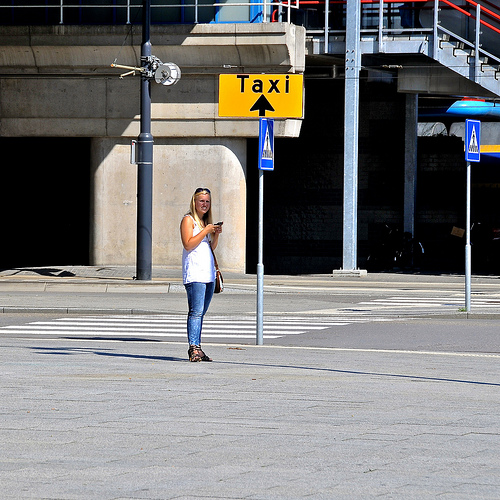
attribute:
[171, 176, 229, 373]
woman — blonde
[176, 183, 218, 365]
woman — blonde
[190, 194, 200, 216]
hair — long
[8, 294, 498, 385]
road — black, paved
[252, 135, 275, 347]
pole — metal 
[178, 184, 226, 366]
woman — standing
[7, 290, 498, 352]
road — black, paved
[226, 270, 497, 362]
road — paved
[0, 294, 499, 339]
lines — thick, white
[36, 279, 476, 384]
street marking — white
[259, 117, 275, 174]
sign — blue, white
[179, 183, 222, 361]
woman — blonde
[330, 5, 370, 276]
gray pole — tall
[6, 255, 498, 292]
sidewalk — long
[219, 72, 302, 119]
yellow/black/taxi sign — Black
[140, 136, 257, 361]
woman — blonde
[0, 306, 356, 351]
lines — white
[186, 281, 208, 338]
jean — blue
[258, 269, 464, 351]
marking — white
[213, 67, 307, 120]
sign — yellow